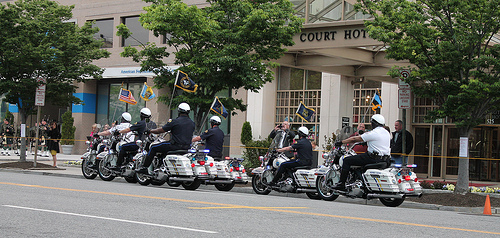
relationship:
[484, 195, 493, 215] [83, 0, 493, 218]
cone in middle of building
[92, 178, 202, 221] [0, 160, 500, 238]
strip in middle of road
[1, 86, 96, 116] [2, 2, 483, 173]
stripe on building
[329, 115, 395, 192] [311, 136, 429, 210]
cops riding motorcycle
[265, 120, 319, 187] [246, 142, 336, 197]
police officer riding motorcycle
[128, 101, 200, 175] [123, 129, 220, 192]
police officer riding motorcycle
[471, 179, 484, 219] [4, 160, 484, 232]
cone on road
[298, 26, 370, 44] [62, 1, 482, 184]
letters on building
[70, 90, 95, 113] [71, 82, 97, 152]
paint on pillar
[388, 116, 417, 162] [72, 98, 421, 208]
guy watching cops